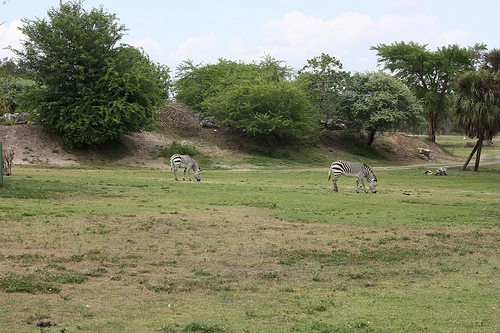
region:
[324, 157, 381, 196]
zebra grazing on a vast field of greenery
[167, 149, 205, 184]
zebra grazing on a vast field of greenery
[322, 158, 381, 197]
black and white animal munching on grass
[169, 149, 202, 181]
black and white animal munching on grass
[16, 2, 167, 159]
large bush in zebra penn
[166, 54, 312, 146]
large bush in zebra penn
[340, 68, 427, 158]
small tree in zebra penn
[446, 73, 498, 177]
small tree in zebra penn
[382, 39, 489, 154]
large tree in zebra penn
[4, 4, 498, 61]
blue sky with puffy white clouds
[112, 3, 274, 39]
the sky is blue and clear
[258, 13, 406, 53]
clouds in the sky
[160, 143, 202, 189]
the zebra on the grass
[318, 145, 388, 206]
the zebra on the grass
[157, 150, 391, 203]
the zebras are grazing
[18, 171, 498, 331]
the grass is patchy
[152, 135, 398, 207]
the zebras are striped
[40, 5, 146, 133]
the large bush behind the zebras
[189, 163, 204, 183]
the head of the zebra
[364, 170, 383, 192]
head of zebra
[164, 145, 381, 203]
two zebras in an open field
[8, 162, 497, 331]
green grass in a field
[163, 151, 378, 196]
two striped zebras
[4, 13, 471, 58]
white fluffy cloud in the sky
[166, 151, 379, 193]
two black and white zebras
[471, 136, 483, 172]
tall thin tree trunk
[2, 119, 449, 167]
rocky hill next to a field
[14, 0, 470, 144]
green trees on a hill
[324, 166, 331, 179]
black tipped zebra tail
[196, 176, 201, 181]
black zebra snout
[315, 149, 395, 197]
a zebra eating grass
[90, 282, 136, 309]
a patch of dirt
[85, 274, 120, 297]
the dirt is brown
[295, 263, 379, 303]
patches of grass in the field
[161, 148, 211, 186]
a black and white zebra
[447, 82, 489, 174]
a tree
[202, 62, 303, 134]
the bush is green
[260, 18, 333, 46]
the cloud is white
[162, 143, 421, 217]
2 zebras are grazing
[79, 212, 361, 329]
brown and green ground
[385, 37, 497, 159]
2 different large trees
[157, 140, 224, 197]
zebra is far away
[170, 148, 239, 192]
zebra is looking down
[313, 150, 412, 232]
zebra with its head down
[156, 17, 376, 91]
blue sky with few clouds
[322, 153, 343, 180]
zebra has long tail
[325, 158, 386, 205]
zebra grazing in grass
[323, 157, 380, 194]
zebra is black and white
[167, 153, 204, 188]
second zebra grazing grass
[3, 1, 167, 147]
large bush on side of hill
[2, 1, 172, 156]
large bush is green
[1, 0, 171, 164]
green bush is large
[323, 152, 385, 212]
black and white zebra grazing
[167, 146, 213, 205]
black and white zebra grazing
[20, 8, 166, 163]
large green tree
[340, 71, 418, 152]
large green tree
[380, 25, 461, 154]
tall green tree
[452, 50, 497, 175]
large green tree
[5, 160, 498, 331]
barren grass field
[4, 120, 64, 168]
hill of dirt